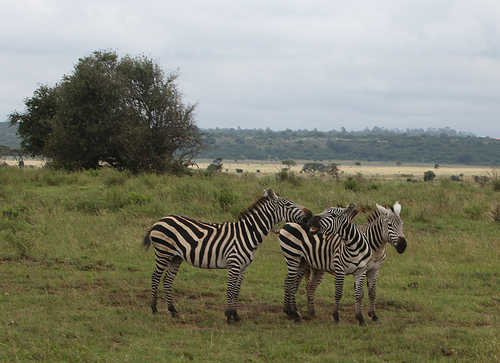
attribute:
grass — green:
[28, 300, 162, 361]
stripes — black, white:
[158, 217, 246, 264]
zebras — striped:
[137, 178, 419, 324]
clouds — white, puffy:
[5, 2, 498, 139]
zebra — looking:
[303, 200, 408, 327]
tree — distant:
[7, 30, 221, 177]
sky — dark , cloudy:
[0, 3, 498, 136]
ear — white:
[371, 198, 390, 220]